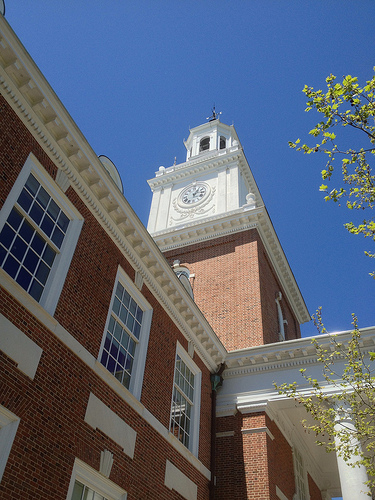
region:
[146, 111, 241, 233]
clock on tower of building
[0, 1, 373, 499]
large red brick building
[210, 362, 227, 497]
rain gutter is in corner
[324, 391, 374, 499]
large white architectural column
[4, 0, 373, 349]
clear and cloudless sky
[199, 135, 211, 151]
opening for bell tower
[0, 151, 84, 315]
left upper floor window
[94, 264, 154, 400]
middle upper floor window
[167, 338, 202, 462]
right upper floor window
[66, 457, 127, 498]
middle ground floor window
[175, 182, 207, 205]
clock on a tower of a court house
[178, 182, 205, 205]
round clock on the top of a court house tower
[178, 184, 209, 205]
clock on top of court house tower reading 2:15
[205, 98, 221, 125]
vane on top of court house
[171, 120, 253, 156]
bell tower on top of court house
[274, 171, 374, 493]
budding tree next to court house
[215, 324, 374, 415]
court house porch awning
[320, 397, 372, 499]
court house porch column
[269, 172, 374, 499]
large tree in front of court house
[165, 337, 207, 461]
1st window next to porch 2nd floor of courthouse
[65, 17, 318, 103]
The sky is blue.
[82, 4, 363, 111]
The skies are clear.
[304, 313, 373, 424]
The branches have leaves.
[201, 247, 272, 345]
The buliding is made of brick.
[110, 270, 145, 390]
This is a window.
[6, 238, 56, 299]
The window is made of glass.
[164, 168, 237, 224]
There is a clock on the tower.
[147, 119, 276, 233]
The tower is white.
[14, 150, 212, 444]
There are three windows visible.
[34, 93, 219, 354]
The building's trim is white.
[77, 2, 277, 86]
this is the sky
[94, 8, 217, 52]
the sky is blue in color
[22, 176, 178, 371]
this is a building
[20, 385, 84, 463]
this is the wall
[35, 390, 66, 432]
the wall is brown in color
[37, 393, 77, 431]
the wall is made of bricks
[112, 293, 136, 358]
this is the window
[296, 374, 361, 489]
this is a tree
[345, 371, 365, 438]
the leaves are green in color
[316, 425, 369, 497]
this is a pillar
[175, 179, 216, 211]
clockface on a white background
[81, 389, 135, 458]
white decoration in a brick wall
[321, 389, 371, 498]
a white column under a porticoshare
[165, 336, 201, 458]
window with 20 panes in a brick building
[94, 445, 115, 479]
white decoration above window in brick building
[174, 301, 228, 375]
decoration on the eave of a brick building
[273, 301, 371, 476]
foliage in front of a white column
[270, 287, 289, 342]
white pipe on the side of a brick building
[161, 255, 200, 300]
arched window in a brick building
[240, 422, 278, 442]
white decoration on the corner of a brick building